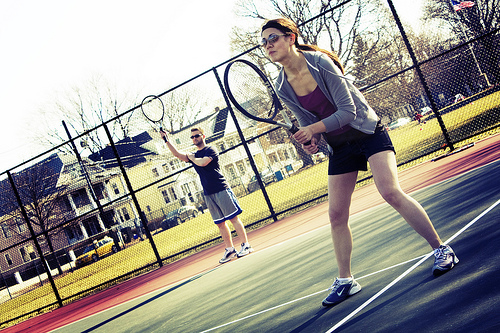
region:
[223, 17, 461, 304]
woman holding a racket tennis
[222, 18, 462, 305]
young woman wearing sunglasess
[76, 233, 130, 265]
yellow car parked on the street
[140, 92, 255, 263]
man holdign racket tennis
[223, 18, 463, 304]
woman wearing black shorts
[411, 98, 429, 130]
child running on the grass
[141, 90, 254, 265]
young man with sunglasses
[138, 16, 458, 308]
two persons holding racket tennis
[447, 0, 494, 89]
post holding a flag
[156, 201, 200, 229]
dark car on the distance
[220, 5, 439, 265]
woman holding tennis racket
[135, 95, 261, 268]
man holding tennis racket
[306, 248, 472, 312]
shoes with nike logo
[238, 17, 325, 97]
woman is wearing sunglasses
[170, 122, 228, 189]
man is wearing sunglasses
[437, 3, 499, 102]
American flag in background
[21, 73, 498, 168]
fence surrounding tennis court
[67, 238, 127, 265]
yellow cab parked beside fence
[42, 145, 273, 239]
row of large houses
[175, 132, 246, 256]
man wearing tshirt and shorts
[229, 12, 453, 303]
woman holding a tennis racket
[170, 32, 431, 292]
man and woman playing tennis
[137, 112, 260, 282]
man standing on tennis court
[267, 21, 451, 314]
woman standing on tennis court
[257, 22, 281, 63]
woman wearing sunglasses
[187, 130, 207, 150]
man wearing black sunglasses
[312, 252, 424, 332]
white lines on ground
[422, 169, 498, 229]
shadow of tree on ground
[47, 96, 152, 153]
tree with no leaves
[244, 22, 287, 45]
Sunglasses on person's face.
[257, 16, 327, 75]
Person has long brown hair.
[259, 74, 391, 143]
Person wearing gray sweatshirt.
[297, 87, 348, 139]
Person wearing purple shirt.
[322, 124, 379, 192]
Person wearing black shorts.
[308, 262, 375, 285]
Person wearing white socks.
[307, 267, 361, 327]
Person wearing Nike tennis shoes.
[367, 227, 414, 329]
White lines on tennis court.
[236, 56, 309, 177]
Person holding tennis racket.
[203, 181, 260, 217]
Person wearing gray, blue, and white shorts.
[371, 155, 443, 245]
the leg of a person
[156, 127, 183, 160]
the arm of a person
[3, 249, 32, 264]
the windows of a building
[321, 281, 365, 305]
a blue and white tennis shoe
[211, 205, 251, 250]
the legs of a person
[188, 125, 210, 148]
the head of a person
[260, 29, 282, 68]
the face of a person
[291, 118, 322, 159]
the hands of a person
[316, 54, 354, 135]
the arm of a person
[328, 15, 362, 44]
the branches of a tree